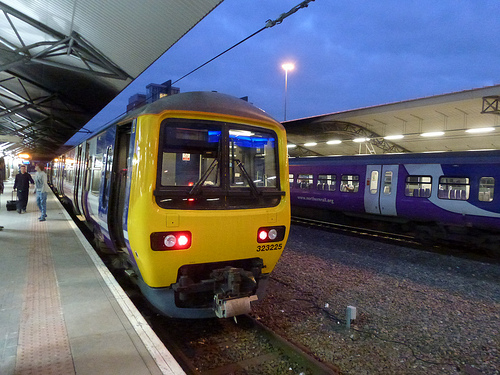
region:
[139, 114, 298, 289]
the front of train is yellow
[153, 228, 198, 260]
the light is on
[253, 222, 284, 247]
the light is on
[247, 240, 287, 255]
the numbers ae 32325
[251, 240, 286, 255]
the numbers are black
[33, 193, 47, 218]
the jeans are blue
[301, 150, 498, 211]
the train is empty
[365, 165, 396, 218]
the door is white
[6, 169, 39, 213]
the man is pulling luggage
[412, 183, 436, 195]
the seats are blue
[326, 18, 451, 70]
this is the sky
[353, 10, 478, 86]
the sky is blue in color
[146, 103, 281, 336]
this is the train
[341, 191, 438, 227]
thew train is blue in color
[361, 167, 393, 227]
this is the door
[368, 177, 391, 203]
the door is white in color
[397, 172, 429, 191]
this is the window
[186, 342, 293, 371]
this is the railway line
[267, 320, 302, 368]
this is a metal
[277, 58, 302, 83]
this is a light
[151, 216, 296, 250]
The headlights of the train.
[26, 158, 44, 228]
A person standing on the walkway.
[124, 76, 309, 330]
Train on the track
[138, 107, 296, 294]
The train is yellow in front.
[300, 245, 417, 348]
Gravel in between the rocks.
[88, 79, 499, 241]
Two trains on the track.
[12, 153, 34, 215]
A person rolling a suitcase.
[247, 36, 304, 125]
A light pole with the shining light.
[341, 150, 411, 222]
The doors on the train.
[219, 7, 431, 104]
The sky is blue.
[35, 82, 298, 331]
modern train stopped at the station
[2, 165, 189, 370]
train station platform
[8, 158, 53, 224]
two passengers on the train platform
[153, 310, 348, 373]
train track next to platform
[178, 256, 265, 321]
front train car coupling mechanism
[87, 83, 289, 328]
train car with yellow face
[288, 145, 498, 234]
train cars colored dark blue and light blue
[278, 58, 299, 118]
light on tall pole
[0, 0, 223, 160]
train platform roof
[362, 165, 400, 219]
train car doors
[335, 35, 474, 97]
this is the sky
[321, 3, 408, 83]
the sky is blue in color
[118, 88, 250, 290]
this is a train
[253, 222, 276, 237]
this is a light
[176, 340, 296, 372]
this is a railway line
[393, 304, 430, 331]
this is the stones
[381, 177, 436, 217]
the train is blue in color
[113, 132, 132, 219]
this is the door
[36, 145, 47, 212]
this is a man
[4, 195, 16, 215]
this is a bag